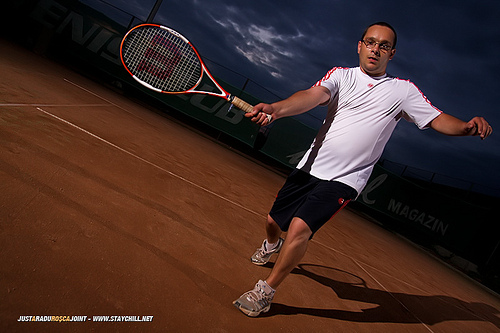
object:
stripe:
[317, 65, 346, 88]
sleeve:
[312, 64, 349, 107]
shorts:
[265, 166, 357, 238]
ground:
[0, 39, 497, 329]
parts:
[338, 198, 347, 207]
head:
[356, 21, 396, 74]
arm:
[270, 66, 342, 117]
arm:
[404, 81, 467, 136]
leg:
[268, 179, 354, 290]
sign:
[364, 82, 378, 90]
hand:
[245, 101, 280, 127]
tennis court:
[0, 46, 499, 332]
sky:
[102, 0, 499, 207]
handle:
[229, 96, 273, 125]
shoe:
[232, 277, 277, 318]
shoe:
[252, 236, 282, 266]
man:
[229, 20, 495, 316]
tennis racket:
[122, 24, 280, 126]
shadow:
[256, 260, 500, 329]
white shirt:
[294, 66, 447, 200]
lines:
[351, 257, 436, 333]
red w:
[134, 34, 186, 81]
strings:
[120, 23, 204, 99]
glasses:
[361, 38, 398, 52]